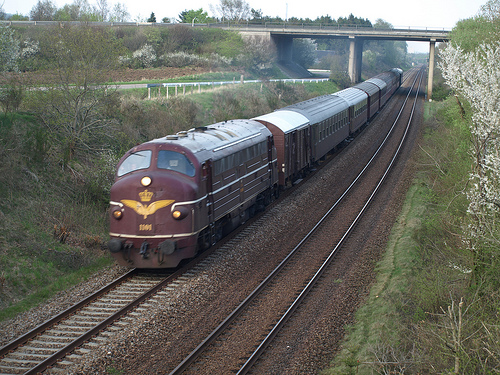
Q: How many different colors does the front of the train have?
A: Two.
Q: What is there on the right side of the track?
A: Green and brown shrubbery.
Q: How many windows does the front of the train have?
A: Two.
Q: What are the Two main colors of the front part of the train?
A: Red and gold.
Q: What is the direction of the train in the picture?
A: South.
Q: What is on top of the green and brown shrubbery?
A: White blooms of a tree.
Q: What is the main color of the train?
A: Burgundy.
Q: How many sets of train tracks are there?
A: Two.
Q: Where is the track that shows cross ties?
A: Left.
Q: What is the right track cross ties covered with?
A: Leafs.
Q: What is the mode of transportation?
A: Train.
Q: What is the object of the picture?
A: A train.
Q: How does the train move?
A: Tracks.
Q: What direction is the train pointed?
A: Lower left.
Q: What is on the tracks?
A: A train.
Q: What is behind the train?
A: Trees.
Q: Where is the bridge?
A: Above the train.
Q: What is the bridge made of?
A: Concrete.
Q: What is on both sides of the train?
A: Grass.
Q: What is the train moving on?
A: Tracks.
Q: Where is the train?
A: On the tracks.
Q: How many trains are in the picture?
A: One.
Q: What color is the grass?
A: Green.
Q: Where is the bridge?
A: Over the train.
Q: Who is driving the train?
A: The engineer.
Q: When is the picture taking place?
A: Daytime.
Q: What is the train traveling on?
A: Tracks.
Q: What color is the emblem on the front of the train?
A: Yellow.